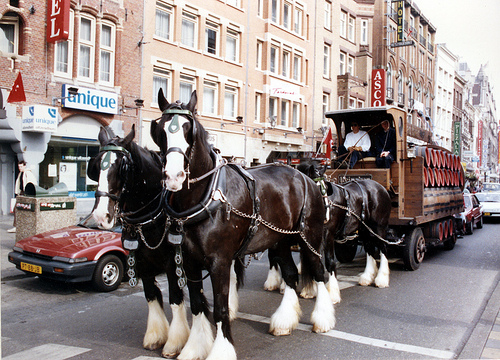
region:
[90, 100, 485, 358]
Horses pulling a carriage.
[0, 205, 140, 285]
A red car is partially hidden by the horses.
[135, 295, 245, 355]
The horses have white fur above their feet.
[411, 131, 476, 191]
Barrels on the carriage.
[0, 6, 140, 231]
A red brick building.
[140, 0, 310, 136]
A tan colored building next to the red building.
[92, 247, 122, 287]
A front tire on the red car.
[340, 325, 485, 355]
A line painted on the street.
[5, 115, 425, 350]
A car next to the horses.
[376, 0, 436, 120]
The brown building has a hotel sign on it.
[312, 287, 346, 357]
White hair on horse's foot.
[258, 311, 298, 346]
White fur on horse's foot.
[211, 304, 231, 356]
White fur on horse's leg.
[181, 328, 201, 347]
White fur on horse's foot.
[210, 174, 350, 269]
Chains along the side of horse.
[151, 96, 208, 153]
Black straps on horse's head.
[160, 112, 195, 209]
Horse has white face.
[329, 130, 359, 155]
Person wearing white shirt.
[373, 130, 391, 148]
Person wearing black shirt.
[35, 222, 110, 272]
Red car near horses.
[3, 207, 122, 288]
red car parked on street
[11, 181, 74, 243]
garbage bin on sidewalk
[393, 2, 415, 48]
sign for hotel on side of building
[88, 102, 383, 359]
horses pulling wagon in street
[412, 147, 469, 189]
barrels stacked in wagon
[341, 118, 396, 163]
men sitting in wagon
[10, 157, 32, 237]
man walking on sidewalk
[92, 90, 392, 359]
horses are brown and white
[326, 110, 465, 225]
wagon made of wood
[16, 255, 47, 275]
license plate is yellow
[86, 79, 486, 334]
horses pulling a beer wagon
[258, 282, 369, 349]
white hairy hooves of a horse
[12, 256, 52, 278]
yellow license plate on a parked car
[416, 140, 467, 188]
beer barrels on a wagon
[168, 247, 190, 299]
bells on a horse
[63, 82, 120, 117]
blue and white sign on store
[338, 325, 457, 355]
white lines on road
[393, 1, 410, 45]
green and yellow sign on building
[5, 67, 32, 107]
red triangular flag on store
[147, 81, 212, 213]
horse with white stripe and pointy ears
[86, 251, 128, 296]
front wheel on a car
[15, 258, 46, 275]
front licence plate on a car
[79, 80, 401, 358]
horses on a street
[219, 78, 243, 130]
window on a building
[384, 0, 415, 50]
sign on a building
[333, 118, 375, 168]
person with a white shirt sitting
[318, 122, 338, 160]
red flag on a pole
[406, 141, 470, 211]
barrels on a wagon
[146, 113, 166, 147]
blinder on a horses eye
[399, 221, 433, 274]
wheel on a wagon